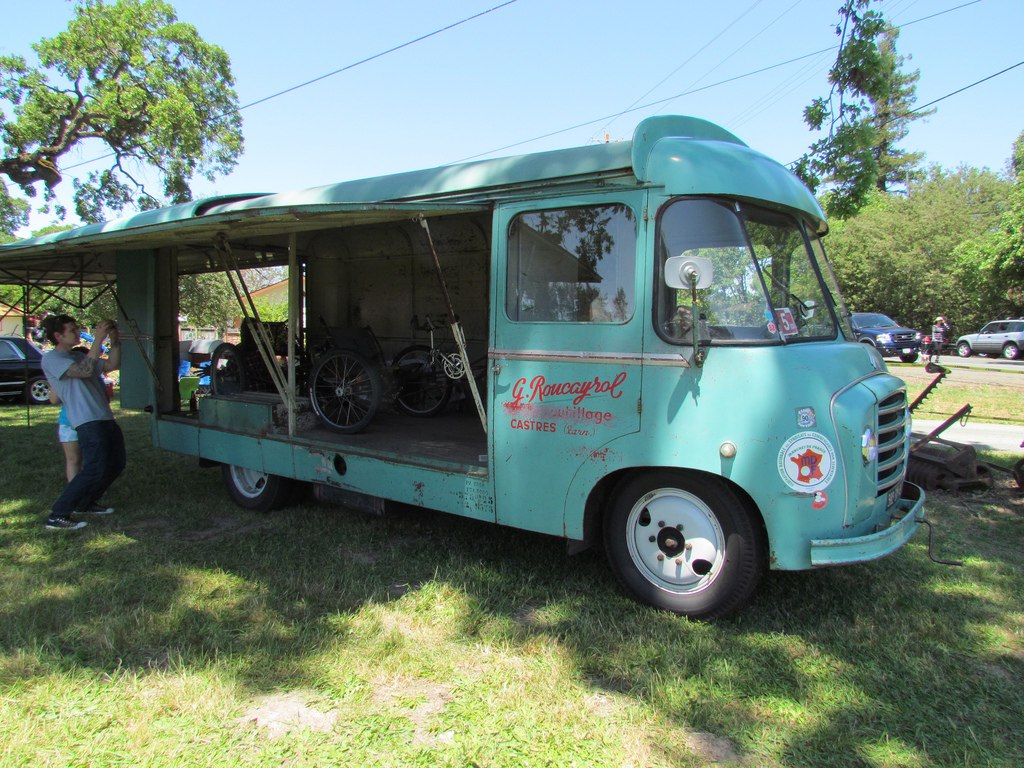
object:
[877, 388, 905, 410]
slat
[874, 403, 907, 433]
slat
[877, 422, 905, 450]
slat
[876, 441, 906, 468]
slat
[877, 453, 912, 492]
slat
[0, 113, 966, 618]
truck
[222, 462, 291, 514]
wheel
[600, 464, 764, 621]
wheel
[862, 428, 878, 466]
headlight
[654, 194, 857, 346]
windshield